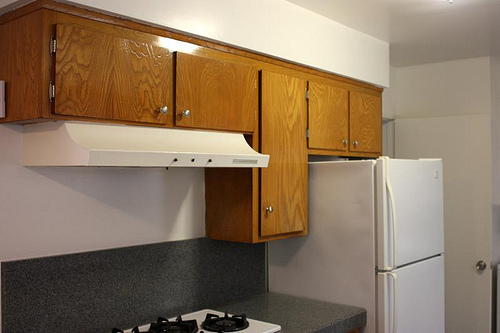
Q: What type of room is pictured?
A: It is a kitchen.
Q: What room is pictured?
A: It is a kitchen.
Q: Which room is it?
A: It is a kitchen.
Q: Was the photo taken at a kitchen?
A: Yes, it was taken in a kitchen.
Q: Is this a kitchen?
A: Yes, it is a kitchen.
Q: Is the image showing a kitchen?
A: Yes, it is showing a kitchen.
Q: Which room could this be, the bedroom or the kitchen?
A: It is the kitchen.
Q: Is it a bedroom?
A: No, it is a kitchen.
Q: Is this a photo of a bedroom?
A: No, the picture is showing a kitchen.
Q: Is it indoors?
A: Yes, it is indoors.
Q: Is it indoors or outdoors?
A: It is indoors.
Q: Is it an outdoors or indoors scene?
A: It is indoors.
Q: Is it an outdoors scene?
A: No, it is indoors.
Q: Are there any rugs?
A: No, there are no rugs.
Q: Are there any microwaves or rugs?
A: No, there are no rugs or microwaves.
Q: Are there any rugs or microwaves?
A: No, there are no rugs or microwaves.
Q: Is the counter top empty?
A: Yes, the counter top is empty.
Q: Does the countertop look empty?
A: Yes, the countertop is empty.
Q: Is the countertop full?
A: No, the countertop is empty.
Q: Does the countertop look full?
A: No, the countertop is empty.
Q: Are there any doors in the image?
A: Yes, there is a door.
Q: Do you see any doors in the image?
A: Yes, there is a door.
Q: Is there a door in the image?
A: Yes, there is a door.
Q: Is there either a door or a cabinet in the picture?
A: Yes, there is a door.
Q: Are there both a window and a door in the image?
A: No, there is a door but no windows.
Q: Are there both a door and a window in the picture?
A: No, there is a door but no windows.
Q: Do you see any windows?
A: No, there are no windows.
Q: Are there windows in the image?
A: No, there are no windows.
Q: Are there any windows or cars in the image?
A: No, there are no windows or cars.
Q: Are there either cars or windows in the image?
A: No, there are no windows or cars.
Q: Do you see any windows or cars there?
A: No, there are no windows or cars.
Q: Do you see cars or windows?
A: No, there are no windows or cars.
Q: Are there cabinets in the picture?
A: Yes, there is a cabinet.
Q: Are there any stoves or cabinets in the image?
A: Yes, there is a cabinet.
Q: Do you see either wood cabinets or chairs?
A: Yes, there is a wood cabinet.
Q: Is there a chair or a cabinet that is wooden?
A: Yes, the cabinet is wooden.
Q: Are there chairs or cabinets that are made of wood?
A: Yes, the cabinet is made of wood.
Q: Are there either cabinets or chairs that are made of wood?
A: Yes, the cabinet is made of wood.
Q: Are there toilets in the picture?
A: No, there are no toilets.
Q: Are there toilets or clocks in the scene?
A: No, there are no toilets or clocks.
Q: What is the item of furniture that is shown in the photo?
A: The piece of furniture is a cabinet.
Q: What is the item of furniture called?
A: The piece of furniture is a cabinet.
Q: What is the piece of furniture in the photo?
A: The piece of furniture is a cabinet.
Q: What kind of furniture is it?
A: The piece of furniture is a cabinet.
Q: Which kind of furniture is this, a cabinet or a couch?
A: This is a cabinet.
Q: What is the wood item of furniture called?
A: The piece of furniture is a cabinet.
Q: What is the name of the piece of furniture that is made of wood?
A: The piece of furniture is a cabinet.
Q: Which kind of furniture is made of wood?
A: The furniture is a cabinet.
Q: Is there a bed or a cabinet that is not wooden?
A: No, there is a cabinet but it is wooden.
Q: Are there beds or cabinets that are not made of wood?
A: No, there is a cabinet but it is made of wood.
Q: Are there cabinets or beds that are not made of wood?
A: No, there is a cabinet but it is made of wood.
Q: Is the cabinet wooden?
A: Yes, the cabinet is wooden.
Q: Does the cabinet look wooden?
A: Yes, the cabinet is wooden.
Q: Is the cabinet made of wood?
A: Yes, the cabinet is made of wood.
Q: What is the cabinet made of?
A: The cabinet is made of wood.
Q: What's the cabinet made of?
A: The cabinet is made of wood.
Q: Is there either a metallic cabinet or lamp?
A: No, there is a cabinet but it is wooden.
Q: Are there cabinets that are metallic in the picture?
A: No, there is a cabinet but it is wooden.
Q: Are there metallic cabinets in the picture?
A: No, there is a cabinet but it is wooden.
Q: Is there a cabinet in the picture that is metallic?
A: No, there is a cabinet but it is wooden.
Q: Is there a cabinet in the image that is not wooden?
A: No, there is a cabinet but it is wooden.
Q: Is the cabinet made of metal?
A: No, the cabinet is made of wood.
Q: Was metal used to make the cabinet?
A: No, the cabinet is made of wood.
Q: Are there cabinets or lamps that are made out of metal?
A: No, there is a cabinet but it is made of wood.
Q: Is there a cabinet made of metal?
A: No, there is a cabinet but it is made of wood.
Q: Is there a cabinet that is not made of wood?
A: No, there is a cabinet but it is made of wood.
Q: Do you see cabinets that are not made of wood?
A: No, there is a cabinet but it is made of wood.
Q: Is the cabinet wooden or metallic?
A: The cabinet is wooden.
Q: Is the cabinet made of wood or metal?
A: The cabinet is made of wood.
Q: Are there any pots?
A: No, there are no pots.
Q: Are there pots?
A: No, there are no pots.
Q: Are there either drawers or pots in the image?
A: No, there are no pots or drawers.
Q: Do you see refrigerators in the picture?
A: Yes, there is a refrigerator.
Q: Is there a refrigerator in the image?
A: Yes, there is a refrigerator.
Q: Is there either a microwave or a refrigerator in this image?
A: Yes, there is a refrigerator.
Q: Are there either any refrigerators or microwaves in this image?
A: Yes, there is a refrigerator.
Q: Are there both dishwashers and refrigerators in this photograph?
A: No, there is a refrigerator but no dishwashers.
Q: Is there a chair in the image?
A: No, there are no chairs.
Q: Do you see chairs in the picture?
A: No, there are no chairs.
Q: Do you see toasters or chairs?
A: No, there are no chairs or toasters.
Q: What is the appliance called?
A: The appliance is a refrigerator.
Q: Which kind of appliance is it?
A: The appliance is a refrigerator.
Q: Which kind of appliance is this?
A: This is a refrigerator.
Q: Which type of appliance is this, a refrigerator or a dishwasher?
A: This is a refrigerator.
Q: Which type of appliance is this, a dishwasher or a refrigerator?
A: This is a refrigerator.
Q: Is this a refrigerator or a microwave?
A: This is a refrigerator.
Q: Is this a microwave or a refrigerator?
A: This is a refrigerator.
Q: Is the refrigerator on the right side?
A: Yes, the refrigerator is on the right of the image.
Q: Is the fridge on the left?
A: No, the fridge is on the right of the image.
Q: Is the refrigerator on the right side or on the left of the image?
A: The refrigerator is on the right of the image.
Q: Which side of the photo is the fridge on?
A: The fridge is on the right of the image.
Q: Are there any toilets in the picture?
A: No, there are no toilets.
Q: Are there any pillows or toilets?
A: No, there are no toilets or pillows.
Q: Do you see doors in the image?
A: Yes, there is a door.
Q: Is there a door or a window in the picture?
A: Yes, there is a door.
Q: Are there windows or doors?
A: Yes, there is a door.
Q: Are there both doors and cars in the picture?
A: No, there is a door but no cars.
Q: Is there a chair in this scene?
A: No, there are no chairs.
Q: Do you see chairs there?
A: No, there are no chairs.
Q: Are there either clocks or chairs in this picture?
A: No, there are no chairs or clocks.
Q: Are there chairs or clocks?
A: No, there are no chairs or clocks.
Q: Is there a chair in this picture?
A: No, there are no chairs.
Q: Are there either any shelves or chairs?
A: No, there are no chairs or shelves.